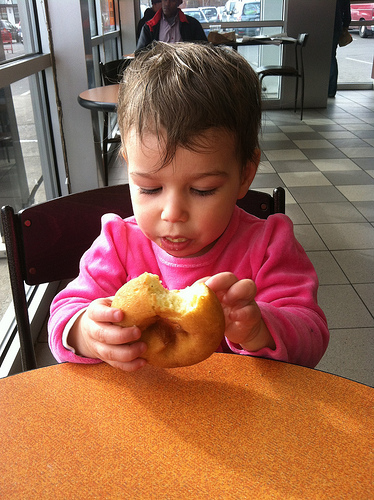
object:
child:
[48, 41, 326, 373]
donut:
[110, 270, 224, 368]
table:
[0, 350, 373, 499]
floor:
[250, 88, 373, 384]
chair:
[1, 185, 285, 370]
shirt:
[48, 206, 322, 367]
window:
[1, 69, 61, 345]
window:
[88, 4, 100, 37]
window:
[240, 27, 284, 93]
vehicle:
[347, 1, 374, 37]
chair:
[252, 32, 308, 119]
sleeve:
[223, 212, 331, 367]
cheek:
[132, 193, 159, 243]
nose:
[161, 187, 188, 223]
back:
[296, 32, 308, 75]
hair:
[117, 38, 262, 174]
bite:
[148, 273, 210, 318]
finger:
[88, 307, 122, 323]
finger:
[91, 322, 141, 346]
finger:
[95, 342, 147, 362]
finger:
[109, 359, 146, 372]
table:
[76, 82, 123, 186]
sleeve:
[49, 211, 124, 364]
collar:
[147, 9, 164, 29]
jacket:
[135, 12, 205, 56]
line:
[345, 56, 374, 66]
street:
[336, 32, 374, 83]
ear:
[237, 145, 260, 200]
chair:
[98, 55, 131, 86]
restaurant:
[1, 1, 373, 499]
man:
[135, 0, 208, 51]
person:
[330, 0, 354, 96]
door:
[336, 1, 373, 90]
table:
[207, 37, 298, 70]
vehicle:
[219, 1, 262, 37]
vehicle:
[179, 7, 207, 33]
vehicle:
[200, 6, 222, 24]